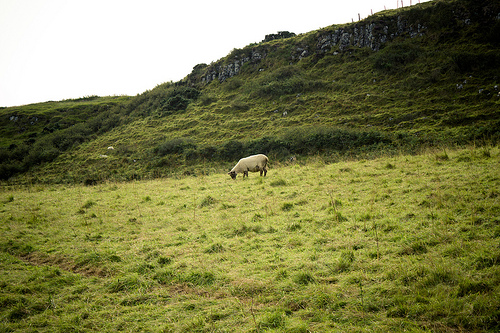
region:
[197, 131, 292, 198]
this is a sheep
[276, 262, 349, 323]
the grass is lush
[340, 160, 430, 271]
the grass is lush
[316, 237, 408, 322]
the grass is lush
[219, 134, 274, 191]
a sheep in the field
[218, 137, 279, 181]
a black and white sheep in the field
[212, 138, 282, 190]
a sheep in the field grazing alone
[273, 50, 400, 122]
Hills in the background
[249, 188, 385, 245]
grass in the field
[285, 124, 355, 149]
Thickets in the background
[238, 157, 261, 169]
White fur of the sheep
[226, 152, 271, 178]
White and black sheep.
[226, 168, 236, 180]
Black sheep head.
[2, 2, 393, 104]
A white sky.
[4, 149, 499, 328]
Light colored green grass field before the hills.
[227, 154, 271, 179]
A white sheep with small white tail.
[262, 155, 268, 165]
A tiny white sheep tail.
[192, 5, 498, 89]
Rocky cliff up past the sheep.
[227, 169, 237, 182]
A sheeps head that is black.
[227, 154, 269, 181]
A grazing white and black sheep.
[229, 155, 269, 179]
White and black grazing sheep with tiny tail.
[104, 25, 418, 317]
a sheep in a green pasture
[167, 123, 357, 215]
a sheep eating grass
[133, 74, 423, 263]
sheep grazing on grass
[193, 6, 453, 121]
mountain cliff rocks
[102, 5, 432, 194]
a green mountain side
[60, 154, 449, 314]
green grass and weeds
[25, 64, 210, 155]
green trees lining a mountain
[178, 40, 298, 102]
straight rock cliffs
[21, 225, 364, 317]
a brown dirt rut in grass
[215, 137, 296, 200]
this is a sheep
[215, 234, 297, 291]
this is grass on the field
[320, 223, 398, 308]
this is grass on the field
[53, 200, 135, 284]
this is grass on the field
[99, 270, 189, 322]
this is grass on the field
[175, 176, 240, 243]
this is grass on the field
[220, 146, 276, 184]
a sheep is grazing in the field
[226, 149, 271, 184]
the head of sheep is black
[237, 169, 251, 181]
front legs of sheep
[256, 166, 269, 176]
back legs of sheep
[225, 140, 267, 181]
a sheep in a field of grass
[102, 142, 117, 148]
a sheep in a field of grass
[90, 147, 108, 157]
a sheep in a field of grass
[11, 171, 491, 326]
a field of grass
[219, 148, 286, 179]
an animal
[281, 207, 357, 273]
grass is tall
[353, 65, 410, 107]
grass on the hill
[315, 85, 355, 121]
hill has grass on it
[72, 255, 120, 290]
dirt in the grass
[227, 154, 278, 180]
animal is white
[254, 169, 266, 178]
back legs of the animal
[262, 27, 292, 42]
a bush on top of the hill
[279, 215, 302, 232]
a batch of grass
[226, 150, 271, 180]
The white lamb in the field.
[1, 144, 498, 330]
The grass field under the hillside.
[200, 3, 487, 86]
Teh rock cliff face.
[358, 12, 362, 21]
The post on the top of the cliff.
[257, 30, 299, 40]
The tree atop the cliff.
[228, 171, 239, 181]
The black face of the sheep.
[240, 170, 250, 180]
The front legs of the sheep.